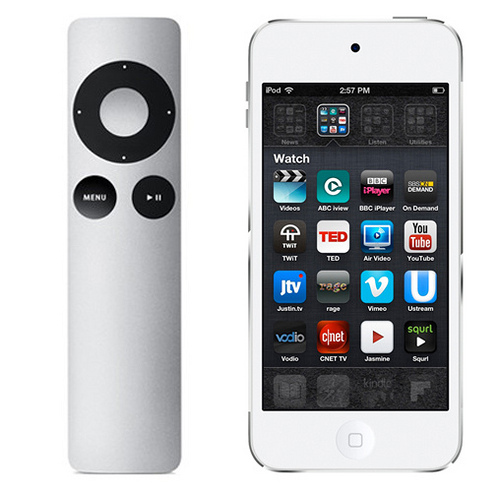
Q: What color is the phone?
A: White.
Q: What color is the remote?
A: Silver.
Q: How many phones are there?
A: One.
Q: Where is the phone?
A: Next to the remote.